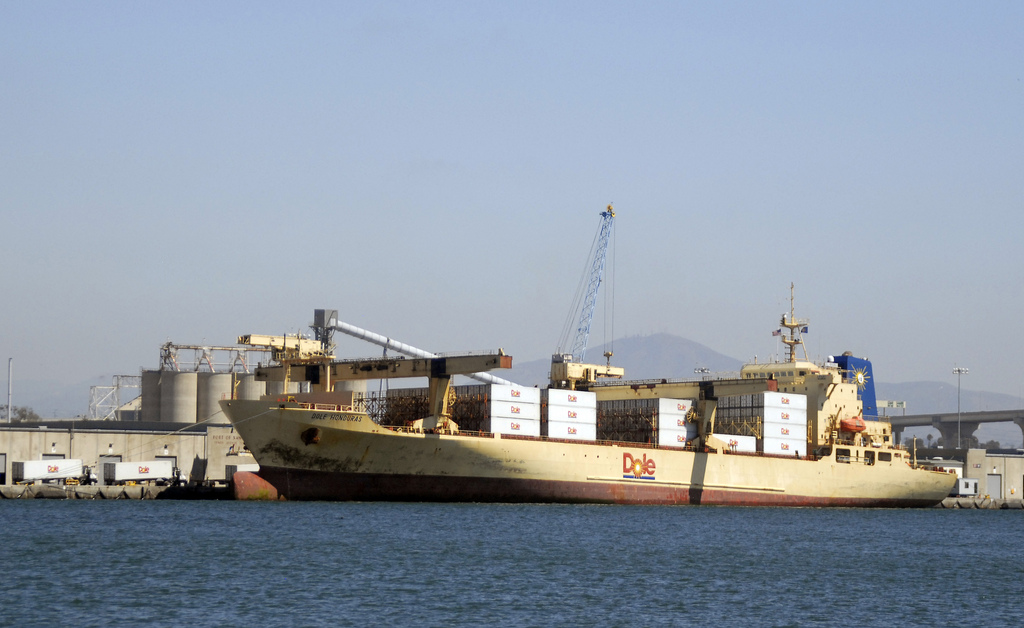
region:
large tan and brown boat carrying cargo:
[223, 318, 993, 533]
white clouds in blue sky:
[395, 17, 478, 116]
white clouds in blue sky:
[859, 47, 926, 108]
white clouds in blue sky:
[898, 182, 955, 253]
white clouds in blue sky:
[186, 148, 245, 194]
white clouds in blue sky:
[53, 90, 127, 155]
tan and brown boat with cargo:
[222, 271, 959, 531]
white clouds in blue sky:
[82, 148, 193, 257]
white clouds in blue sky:
[209, 176, 285, 241]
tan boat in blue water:
[189, 198, 983, 544]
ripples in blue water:
[230, 534, 382, 586]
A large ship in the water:
[220, 334, 963, 503]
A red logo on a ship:
[614, 449, 662, 487]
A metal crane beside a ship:
[570, 205, 613, 367]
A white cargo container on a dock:
[103, 456, 174, 483]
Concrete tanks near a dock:
[138, 366, 295, 433]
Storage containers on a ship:
[371, 386, 600, 441]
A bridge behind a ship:
[887, 399, 1021, 451]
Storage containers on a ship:
[596, 395, 689, 449]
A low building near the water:
[1, 424, 258, 489]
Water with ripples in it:
[8, 496, 1011, 624]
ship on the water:
[236, 307, 957, 517]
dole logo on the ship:
[613, 446, 667, 488]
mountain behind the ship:
[486, 304, 744, 377]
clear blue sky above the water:
[9, 7, 1021, 444]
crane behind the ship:
[543, 190, 633, 368]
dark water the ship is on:
[9, 472, 1022, 625]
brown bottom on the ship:
[263, 456, 817, 521]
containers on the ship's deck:
[410, 363, 804, 458]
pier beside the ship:
[7, 442, 265, 497]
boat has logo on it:
[596, 458, 692, 498]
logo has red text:
[611, 440, 689, 501]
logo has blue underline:
[602, 470, 672, 496]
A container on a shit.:
[539, 402, 600, 426]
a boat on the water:
[228, 312, 830, 575]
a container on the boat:
[406, 376, 511, 460]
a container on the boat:
[529, 393, 607, 445]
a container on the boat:
[620, 402, 666, 442]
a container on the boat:
[746, 291, 836, 472]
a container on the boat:
[406, 320, 508, 437]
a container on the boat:
[552, 361, 595, 504]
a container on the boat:
[555, 355, 669, 492]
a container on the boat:
[684, 364, 806, 486]